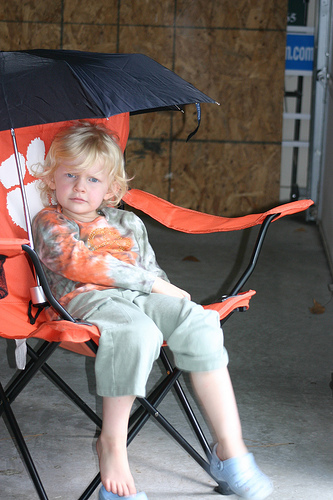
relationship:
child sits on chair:
[32, 118, 275, 496] [0, 111, 313, 498]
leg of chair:
[59, 337, 234, 495] [0, 111, 313, 498]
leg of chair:
[0, 368, 184, 498] [0, 111, 313, 498]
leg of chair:
[17, 336, 103, 431] [0, 111, 313, 498]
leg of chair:
[7, 339, 60, 411] [0, 111, 313, 498]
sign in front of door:
[280, 26, 321, 67] [303, 3, 332, 249]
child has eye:
[32, 118, 275, 496] [87, 177, 99, 185]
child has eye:
[32, 118, 275, 496] [62, 169, 76, 180]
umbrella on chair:
[0, 50, 220, 309] [0, 111, 313, 498]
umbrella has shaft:
[0, 50, 220, 324] [8, 128, 48, 305]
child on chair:
[32, 118, 275, 496] [0, 48, 329, 476]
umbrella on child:
[0, 50, 220, 324] [32, 118, 275, 496]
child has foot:
[32, 118, 275, 496] [90, 426, 142, 498]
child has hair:
[17, 100, 310, 432] [37, 115, 133, 219]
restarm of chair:
[133, 183, 315, 231] [4, 113, 286, 455]